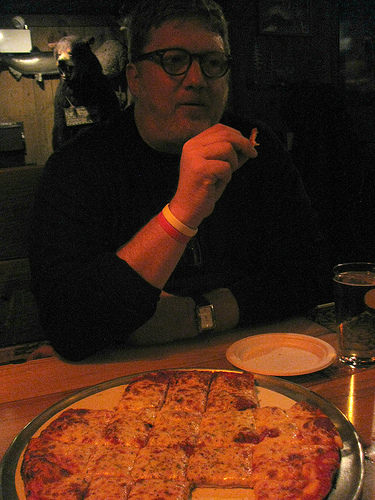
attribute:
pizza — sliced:
[24, 369, 344, 495]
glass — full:
[335, 262, 374, 368]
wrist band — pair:
[160, 204, 198, 239]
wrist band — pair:
[155, 210, 191, 244]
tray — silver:
[223, 317, 330, 395]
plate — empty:
[224, 330, 335, 377]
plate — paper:
[229, 326, 335, 379]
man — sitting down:
[20, 1, 333, 366]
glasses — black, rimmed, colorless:
[125, 43, 239, 88]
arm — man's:
[76, 176, 222, 283]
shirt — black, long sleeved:
[31, 105, 340, 361]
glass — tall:
[330, 258, 373, 371]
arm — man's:
[22, 135, 195, 367]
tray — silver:
[0, 360, 355, 498]